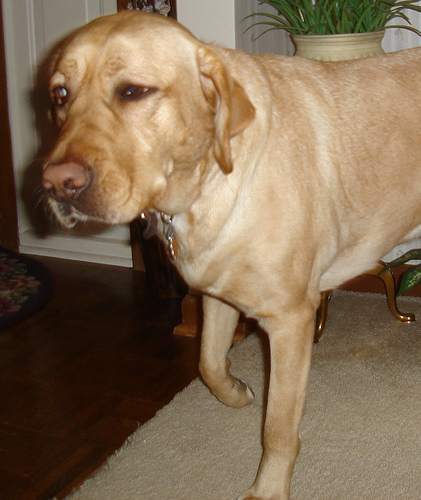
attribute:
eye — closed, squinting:
[116, 75, 162, 102]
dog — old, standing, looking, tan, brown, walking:
[34, 10, 420, 500]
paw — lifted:
[214, 376, 258, 412]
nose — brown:
[39, 161, 92, 197]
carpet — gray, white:
[60, 290, 420, 499]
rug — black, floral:
[0, 245, 55, 337]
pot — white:
[288, 28, 389, 66]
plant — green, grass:
[245, 0, 419, 38]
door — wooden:
[1, 84, 22, 265]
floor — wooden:
[0, 256, 238, 498]